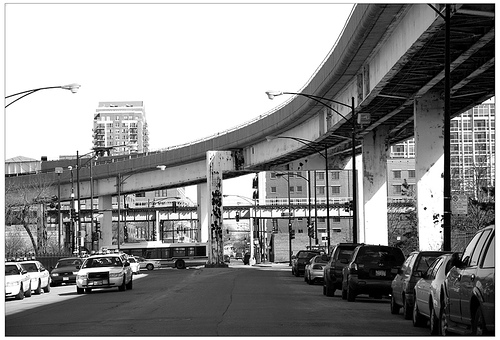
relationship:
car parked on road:
[434, 223, 496, 337] [6, 255, 446, 335]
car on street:
[434, 223, 496, 337] [140, 266, 357, 337]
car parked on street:
[322, 244, 394, 295] [143, 265, 334, 336]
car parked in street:
[337, 242, 408, 303] [4, 253, 452, 338]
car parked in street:
[434, 223, 496, 337] [140, 269, 302, 332]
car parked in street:
[62, 240, 166, 301] [4, 253, 452, 338]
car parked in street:
[18, 253, 53, 292] [4, 253, 452, 338]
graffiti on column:
[198, 159, 243, 272] [203, 148, 240, 268]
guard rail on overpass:
[217, 186, 356, 216] [197, 150, 384, 246]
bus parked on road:
[115, 244, 214, 273] [7, 265, 411, 339]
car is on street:
[286, 242, 324, 279] [9, 249, 444, 334]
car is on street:
[434, 223, 496, 337] [8, 264, 455, 339]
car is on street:
[409, 249, 466, 331] [8, 264, 455, 339]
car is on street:
[388, 247, 451, 317] [8, 264, 455, 339]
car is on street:
[342, 245, 408, 302] [8, 264, 455, 339]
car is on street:
[322, 244, 385, 299] [8, 264, 455, 339]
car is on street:
[322, 244, 385, 299] [212, 245, 345, 338]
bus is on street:
[115, 244, 214, 273] [107, 264, 359, 339]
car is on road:
[304, 255, 330, 285] [12, 238, 442, 335]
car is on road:
[291, 250, 322, 276] [135, 248, 335, 338]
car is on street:
[409, 249, 466, 331] [4, 253, 452, 338]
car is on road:
[388, 247, 451, 317] [12, 238, 442, 335]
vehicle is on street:
[341, 243, 404, 299] [4, 253, 452, 338]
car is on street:
[322, 244, 385, 299] [173, 224, 357, 320]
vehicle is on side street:
[3, 262, 30, 297] [5, 252, 115, 306]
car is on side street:
[18, 259, 53, 292] [5, 252, 115, 306]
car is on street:
[18, 259, 53, 292] [4, 269, 400, 338]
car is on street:
[51, 256, 88, 285] [1, 267, 438, 334]